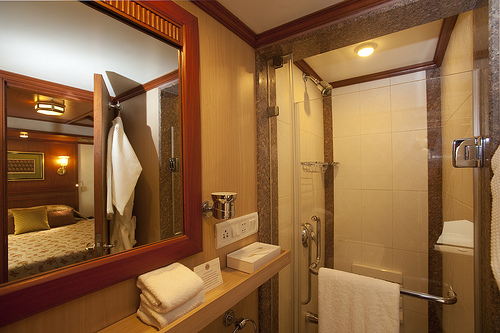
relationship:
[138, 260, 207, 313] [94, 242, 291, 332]
towel on shelf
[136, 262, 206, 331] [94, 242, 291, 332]
towel on shelf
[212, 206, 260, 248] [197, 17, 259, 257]
outlet on wall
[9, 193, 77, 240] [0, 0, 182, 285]
pillows in mirror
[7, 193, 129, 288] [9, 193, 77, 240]
bed in pillows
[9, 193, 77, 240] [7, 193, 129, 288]
pillows on bed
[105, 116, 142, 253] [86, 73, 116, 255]
towel on door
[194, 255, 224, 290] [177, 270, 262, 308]
sign on shelf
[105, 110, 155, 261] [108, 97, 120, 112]
robe hung on hook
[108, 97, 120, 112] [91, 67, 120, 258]
hook behind door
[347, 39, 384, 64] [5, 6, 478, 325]
fixture in bathroom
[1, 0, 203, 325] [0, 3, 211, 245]
mirror with wood frame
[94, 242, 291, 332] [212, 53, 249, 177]
shelf on wall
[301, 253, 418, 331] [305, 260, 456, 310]
towel on bar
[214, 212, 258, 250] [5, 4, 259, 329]
outlet on wall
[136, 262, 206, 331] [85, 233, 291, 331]
towel on shelf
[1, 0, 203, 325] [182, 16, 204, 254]
mirror has frame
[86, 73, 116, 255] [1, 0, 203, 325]
door reflects on mirror